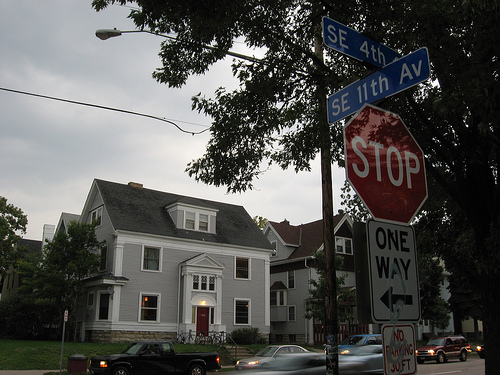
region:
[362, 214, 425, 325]
a one way arrow sign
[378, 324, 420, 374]
a no parking sign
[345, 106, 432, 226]
a red stop sign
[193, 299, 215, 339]
a red front door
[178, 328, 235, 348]
bicycles parked outside a house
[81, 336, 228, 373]
a pickup truck with headlights on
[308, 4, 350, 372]
a tall wooden pole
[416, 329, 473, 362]
a red sport utility vehicle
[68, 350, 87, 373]
a plastic trash can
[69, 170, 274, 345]
a grey house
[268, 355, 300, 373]
blurred view of passing vehicle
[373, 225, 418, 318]
a one way only sign controls traffic flow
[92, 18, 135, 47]
dusk to dawn light fixture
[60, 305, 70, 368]
an unreadable sign on the sidewalk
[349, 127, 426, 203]
a red and white stop sign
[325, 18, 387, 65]
blue sign with white letters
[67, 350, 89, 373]
a curbside trash bin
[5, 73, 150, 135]
an overhead power line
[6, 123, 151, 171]
the sky appears overcast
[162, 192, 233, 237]
a dormer of a house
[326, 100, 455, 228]
a stop sign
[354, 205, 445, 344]
a one way street sign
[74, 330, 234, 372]
a black pickup truck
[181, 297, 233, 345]
a red front door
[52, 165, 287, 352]
a grey house with white trimwork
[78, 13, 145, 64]
a street lamp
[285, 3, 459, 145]
blue street name signes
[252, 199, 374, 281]
a house with a brown roof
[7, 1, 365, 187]
grey cloudy skies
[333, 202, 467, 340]
a road sign with graffiti on it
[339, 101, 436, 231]
a stop sign at an intersection in a residential area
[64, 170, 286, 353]
a large gray home with a red door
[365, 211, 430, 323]
a "one way" sign underneath the stop sign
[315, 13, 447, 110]
street signs on top of the stop sign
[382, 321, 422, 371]
a "no parking 30 feet" sign under the "one way" sign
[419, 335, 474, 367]
an SUV on the street with it's lights on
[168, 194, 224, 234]
an attic gable on the roof of a house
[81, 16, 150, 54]
a street light on a residential street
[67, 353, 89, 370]
a garbage bin on the side of the street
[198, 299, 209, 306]
a light on the front of the large house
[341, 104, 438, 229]
Red stop sign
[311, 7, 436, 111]
Two blue street signs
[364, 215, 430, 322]
One white street sign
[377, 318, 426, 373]
Red and white no parking sign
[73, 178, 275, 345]
Grey and white house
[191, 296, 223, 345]
A red door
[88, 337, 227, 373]
A black truck with its lights on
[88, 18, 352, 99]
A street light that is not on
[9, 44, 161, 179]
Grey cloudy sky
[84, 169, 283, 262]
Black shingles on roof